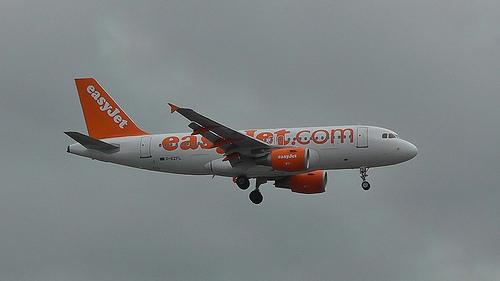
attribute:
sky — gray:
[0, 2, 497, 279]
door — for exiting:
[139, 135, 151, 157]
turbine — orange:
[269, 137, 314, 169]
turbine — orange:
[287, 167, 330, 194]